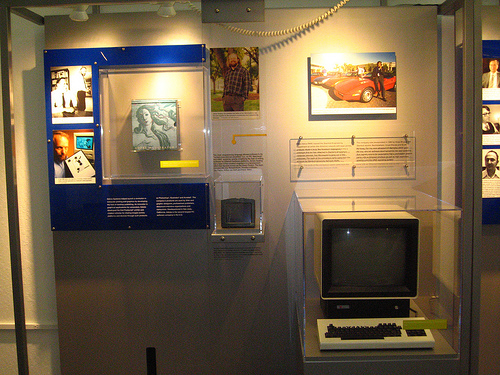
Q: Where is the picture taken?
A: A museum.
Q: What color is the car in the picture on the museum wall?
A: Red.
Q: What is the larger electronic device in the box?
A: A computer.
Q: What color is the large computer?
A: Black and white.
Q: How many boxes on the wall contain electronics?
A: Two.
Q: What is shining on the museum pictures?
A: Lights.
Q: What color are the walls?
A: White.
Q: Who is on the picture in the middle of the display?
A: A man.